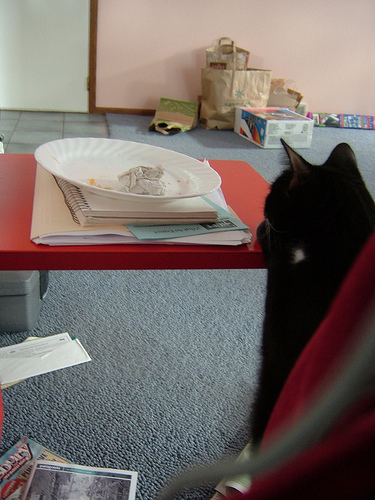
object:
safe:
[0, 270, 51, 334]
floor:
[2, 106, 374, 498]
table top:
[0, 152, 272, 270]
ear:
[278, 137, 314, 175]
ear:
[326, 141, 358, 166]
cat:
[247, 137, 375, 497]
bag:
[199, 67, 273, 131]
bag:
[205, 36, 251, 71]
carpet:
[2, 115, 373, 498]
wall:
[95, 0, 375, 116]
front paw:
[256, 219, 269, 255]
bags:
[145, 96, 198, 136]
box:
[233, 104, 315, 150]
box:
[339, 112, 375, 130]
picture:
[239, 108, 267, 149]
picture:
[243, 106, 313, 121]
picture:
[320, 112, 342, 125]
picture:
[309, 112, 373, 128]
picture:
[224, 87, 251, 107]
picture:
[209, 61, 226, 70]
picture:
[156, 97, 198, 118]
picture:
[200, 219, 238, 231]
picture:
[24, 462, 133, 500]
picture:
[0, 432, 71, 498]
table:
[0, 152, 270, 270]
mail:
[0, 332, 92, 392]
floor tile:
[63, 113, 106, 123]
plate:
[33, 136, 222, 204]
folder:
[29, 158, 254, 250]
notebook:
[50, 173, 219, 228]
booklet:
[0, 432, 75, 500]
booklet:
[18, 456, 139, 500]